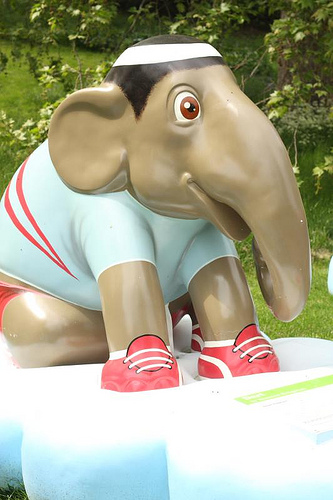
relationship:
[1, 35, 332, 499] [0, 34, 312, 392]
statue of elephant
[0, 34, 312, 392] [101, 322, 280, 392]
elephant wearing shoes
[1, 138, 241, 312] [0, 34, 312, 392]
shirt on elephant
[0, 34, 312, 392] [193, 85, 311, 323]
elephant has a trunk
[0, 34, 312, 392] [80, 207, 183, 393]
elephant has a leg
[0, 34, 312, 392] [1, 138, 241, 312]
elephant wearing shirt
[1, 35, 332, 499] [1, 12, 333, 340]
statue on grass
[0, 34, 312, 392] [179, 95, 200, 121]
elephant has an eye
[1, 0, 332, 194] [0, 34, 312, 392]
leaves around elephant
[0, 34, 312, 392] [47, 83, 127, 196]
elephant has an ear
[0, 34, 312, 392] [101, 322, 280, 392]
elephant has shoes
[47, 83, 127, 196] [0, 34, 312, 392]
ear on elephant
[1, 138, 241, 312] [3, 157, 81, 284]
shirt has a red stripe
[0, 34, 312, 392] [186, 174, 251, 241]
elephant has a mouth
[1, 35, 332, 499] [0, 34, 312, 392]
statue of an elephant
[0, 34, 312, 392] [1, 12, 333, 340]
elephant surrounded by grass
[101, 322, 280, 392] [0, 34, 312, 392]
shoes on elephant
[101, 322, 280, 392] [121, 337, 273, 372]
shoes have shoelaces